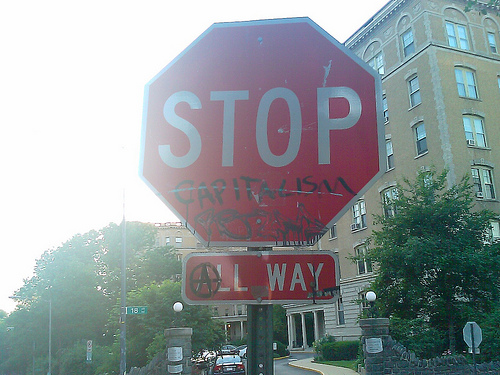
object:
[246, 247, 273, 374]
pole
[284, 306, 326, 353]
columns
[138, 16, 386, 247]
sign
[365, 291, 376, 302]
lamp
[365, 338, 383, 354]
lsign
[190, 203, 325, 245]
graffiti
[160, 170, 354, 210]
black graffiti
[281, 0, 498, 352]
building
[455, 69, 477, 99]
window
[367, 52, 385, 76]
window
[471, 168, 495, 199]
window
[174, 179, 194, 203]
words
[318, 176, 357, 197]
word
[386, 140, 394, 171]
window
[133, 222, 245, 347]
building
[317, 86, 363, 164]
letter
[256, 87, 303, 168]
letter o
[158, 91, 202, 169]
letter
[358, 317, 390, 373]
pillar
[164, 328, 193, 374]
pillar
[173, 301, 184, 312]
light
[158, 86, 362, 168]
stop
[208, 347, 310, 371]
street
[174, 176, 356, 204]
capitalism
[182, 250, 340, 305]
sign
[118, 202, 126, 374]
post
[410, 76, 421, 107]
window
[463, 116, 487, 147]
window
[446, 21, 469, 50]
window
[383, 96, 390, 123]
window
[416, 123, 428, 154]
window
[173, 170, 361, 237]
spraypaint